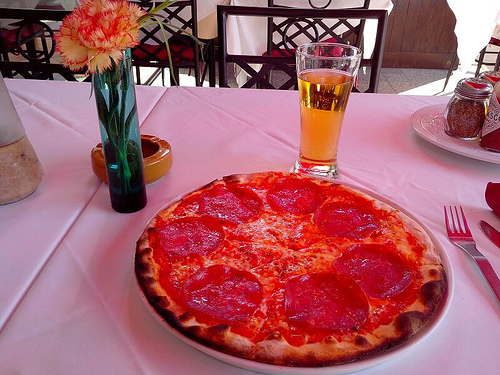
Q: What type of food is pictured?
A: Pizza.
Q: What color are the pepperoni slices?
A: Red.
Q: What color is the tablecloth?
A: White.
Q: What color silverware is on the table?
A: SIlver.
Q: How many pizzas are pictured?
A: One.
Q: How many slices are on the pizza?
A: Eight.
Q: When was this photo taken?
A: Day time.